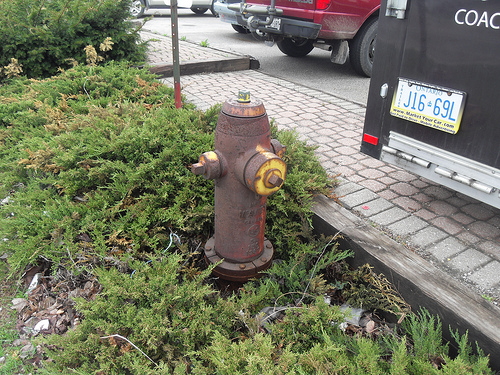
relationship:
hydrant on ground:
[189, 87, 286, 278] [8, 77, 493, 368]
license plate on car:
[389, 76, 467, 134] [357, 1, 497, 211]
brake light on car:
[362, 132, 379, 146] [357, 1, 497, 211]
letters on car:
[453, 7, 498, 27] [357, 1, 497, 211]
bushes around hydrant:
[0, 59, 498, 374] [189, 87, 286, 278]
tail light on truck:
[311, 0, 333, 20] [236, 0, 379, 72]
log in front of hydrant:
[329, 265, 479, 346] [189, 87, 286, 278]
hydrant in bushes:
[193, 90, 289, 285] [0, 59, 498, 374]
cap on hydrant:
[253, 159, 285, 191] [189, 87, 286, 278]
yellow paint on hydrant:
[254, 156, 291, 193] [183, 88, 297, 283]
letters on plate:
[402, 91, 454, 121] [389, 76, 464, 136]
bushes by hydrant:
[0, 59, 498, 374] [189, 87, 286, 278]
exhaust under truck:
[311, 39, 333, 51] [211, 0, 385, 76]